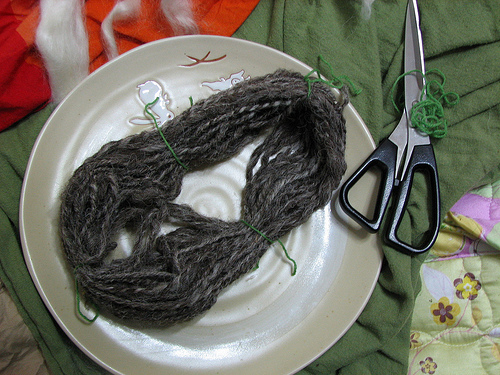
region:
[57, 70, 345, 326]
gray yarn on a plate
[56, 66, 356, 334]
green thread is holding the yarn together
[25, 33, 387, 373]
the plate is white with a bunny motif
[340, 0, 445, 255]
the shears are have black handles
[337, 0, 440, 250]
the scissors have silver blades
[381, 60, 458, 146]
green thread is sitting on the shears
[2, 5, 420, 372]
the plate is on top of green flannel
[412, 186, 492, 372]
quilt is under the flannel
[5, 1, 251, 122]
orange material is under the plate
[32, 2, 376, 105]
white hair is under the plate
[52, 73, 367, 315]
a pile of gray yarn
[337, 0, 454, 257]
black and silver scissors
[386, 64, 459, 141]
thin green yarn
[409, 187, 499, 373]
a yellow and purple quilt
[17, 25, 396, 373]
a white ceramic plate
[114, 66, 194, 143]
a white bunny design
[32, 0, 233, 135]
fake white hairs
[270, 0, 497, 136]
green cotton fabric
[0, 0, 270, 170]
orange and red fabric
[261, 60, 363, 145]
green yarn ties holding gray yarn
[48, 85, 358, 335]
Gray loop of yarn.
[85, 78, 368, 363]
Green string wrapped around gray yarn.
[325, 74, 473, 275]
Scissors with a black handle.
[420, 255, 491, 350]
Purple and yellow flowers.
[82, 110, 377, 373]
Gray yarn on a white plate.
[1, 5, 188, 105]
White cotton next to colorful fabric.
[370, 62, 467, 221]
Green yarn on scissors.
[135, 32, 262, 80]
Bird etched into plate.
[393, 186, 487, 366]
purple and yellow blanket.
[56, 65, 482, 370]
Blankets with a plate on top.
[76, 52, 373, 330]
the yarn is gray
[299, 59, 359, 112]
the threads are green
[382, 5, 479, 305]
the scissors are black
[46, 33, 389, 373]
the plate is beige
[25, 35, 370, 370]
the plate is circle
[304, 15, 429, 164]
the blanket is green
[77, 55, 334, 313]
yarn is on the plate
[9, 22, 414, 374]
the plate is on the bed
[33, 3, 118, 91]
the fur is white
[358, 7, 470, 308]
scissors on the bed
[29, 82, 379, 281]
black yarn on a plate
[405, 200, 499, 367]
a blanket with a flowers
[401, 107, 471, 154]
cut yard sitting on scissors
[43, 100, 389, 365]
a white plate sitting on fabric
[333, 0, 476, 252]
a black pair of scissors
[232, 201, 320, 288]
green yarn scraps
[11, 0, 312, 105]
red fabric on a table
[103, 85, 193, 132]
creatures embossed in the plate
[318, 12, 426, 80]
green fabric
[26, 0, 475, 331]
an arts and crafts project